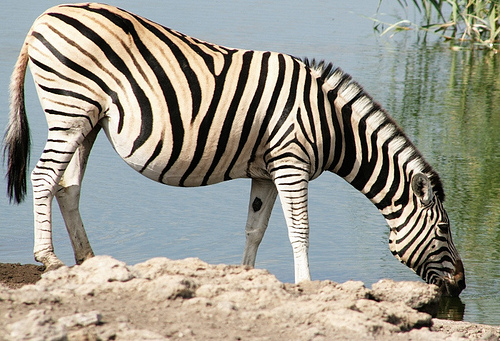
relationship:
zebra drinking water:
[3, 0, 468, 301] [2, 0, 500, 324]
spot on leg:
[252, 196, 262, 212] [243, 178, 279, 265]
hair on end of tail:
[5, 120, 31, 205] [0, 27, 35, 203]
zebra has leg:
[3, 0, 468, 301] [243, 178, 279, 265]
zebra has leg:
[3, 0, 468, 301] [271, 160, 319, 285]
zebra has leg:
[3, 0, 468, 301] [29, 104, 104, 268]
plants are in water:
[371, 1, 499, 54] [2, 0, 500, 324]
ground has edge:
[1, 256, 499, 340] [50, 252, 427, 319]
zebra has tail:
[3, 0, 468, 301] [0, 27, 35, 203]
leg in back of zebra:
[29, 104, 104, 268] [3, 0, 468, 301]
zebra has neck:
[3, 0, 468, 301] [317, 73, 412, 221]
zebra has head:
[3, 0, 468, 301] [388, 169, 468, 296]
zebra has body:
[3, 0, 468, 301] [28, 2, 339, 186]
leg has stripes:
[271, 160, 319, 285] [274, 171, 309, 253]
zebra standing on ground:
[3, 0, 468, 301] [1, 256, 499, 340]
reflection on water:
[384, 40, 499, 270] [2, 0, 500, 324]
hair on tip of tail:
[5, 120, 31, 205] [0, 27, 35, 203]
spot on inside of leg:
[252, 196, 262, 212] [243, 178, 279, 265]